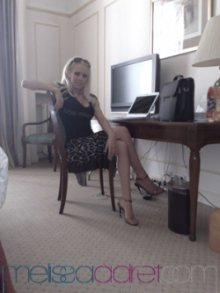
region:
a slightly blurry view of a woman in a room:
[0, 1, 216, 256]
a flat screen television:
[105, 46, 160, 110]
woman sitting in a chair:
[18, 55, 163, 225]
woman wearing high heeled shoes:
[108, 165, 165, 231]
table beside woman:
[92, 116, 217, 241]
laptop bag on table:
[154, 63, 209, 136]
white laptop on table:
[104, 88, 164, 136]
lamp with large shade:
[188, 8, 215, 120]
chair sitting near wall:
[15, 88, 72, 170]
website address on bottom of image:
[1, 258, 219, 291]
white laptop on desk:
[106, 81, 156, 130]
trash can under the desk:
[156, 114, 200, 229]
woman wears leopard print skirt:
[33, 56, 124, 177]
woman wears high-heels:
[105, 161, 165, 234]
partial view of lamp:
[145, 16, 218, 116]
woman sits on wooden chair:
[15, 47, 152, 214]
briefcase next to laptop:
[111, 55, 203, 126]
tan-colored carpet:
[0, 160, 218, 290]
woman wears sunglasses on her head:
[52, 51, 106, 108]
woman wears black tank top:
[26, 52, 103, 141]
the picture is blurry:
[37, 115, 219, 280]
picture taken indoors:
[16, 84, 204, 284]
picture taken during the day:
[3, 86, 191, 286]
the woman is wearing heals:
[105, 180, 172, 227]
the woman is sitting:
[35, 92, 168, 224]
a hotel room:
[6, 90, 193, 286]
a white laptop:
[123, 88, 164, 141]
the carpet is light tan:
[37, 226, 95, 266]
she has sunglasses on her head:
[68, 59, 93, 69]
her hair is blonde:
[55, 66, 114, 114]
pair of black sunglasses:
[66, 51, 92, 67]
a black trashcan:
[167, 176, 198, 247]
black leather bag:
[159, 73, 199, 128]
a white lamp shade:
[192, 12, 219, 67]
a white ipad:
[128, 93, 154, 119]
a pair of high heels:
[117, 176, 164, 227]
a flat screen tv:
[110, 60, 160, 115]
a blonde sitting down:
[22, 52, 166, 207]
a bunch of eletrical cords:
[143, 141, 202, 200]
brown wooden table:
[109, 117, 218, 216]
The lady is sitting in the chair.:
[49, 61, 113, 168]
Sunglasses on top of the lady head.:
[71, 51, 92, 70]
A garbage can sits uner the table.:
[167, 173, 194, 238]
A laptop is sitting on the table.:
[105, 100, 156, 128]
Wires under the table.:
[147, 143, 195, 170]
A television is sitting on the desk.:
[101, 57, 177, 112]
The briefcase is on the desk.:
[160, 79, 199, 126]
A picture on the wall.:
[137, 5, 207, 65]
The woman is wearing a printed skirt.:
[67, 134, 113, 158]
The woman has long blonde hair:
[61, 59, 99, 105]